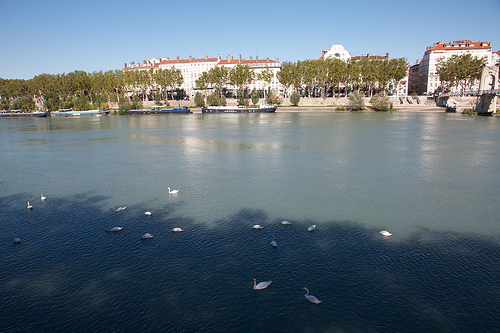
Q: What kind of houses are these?
A: Mansions.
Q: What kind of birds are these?
A: Ducks.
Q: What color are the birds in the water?
A: White.